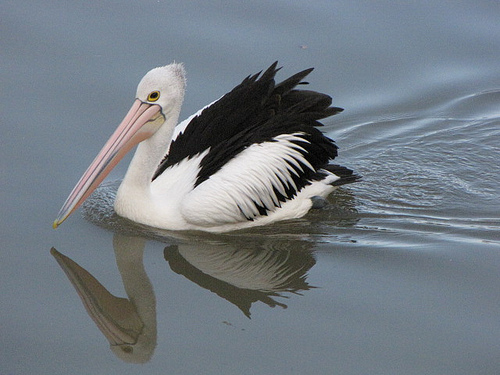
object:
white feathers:
[179, 192, 234, 224]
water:
[0, 0, 500, 375]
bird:
[52, 59, 363, 234]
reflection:
[49, 230, 320, 365]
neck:
[114, 116, 179, 215]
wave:
[313, 87, 499, 245]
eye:
[147, 90, 161, 102]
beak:
[51, 98, 163, 230]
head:
[52, 61, 188, 229]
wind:
[200, 125, 367, 226]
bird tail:
[242, 59, 345, 127]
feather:
[245, 131, 315, 212]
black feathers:
[227, 60, 345, 128]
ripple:
[316, 79, 500, 250]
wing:
[178, 110, 324, 226]